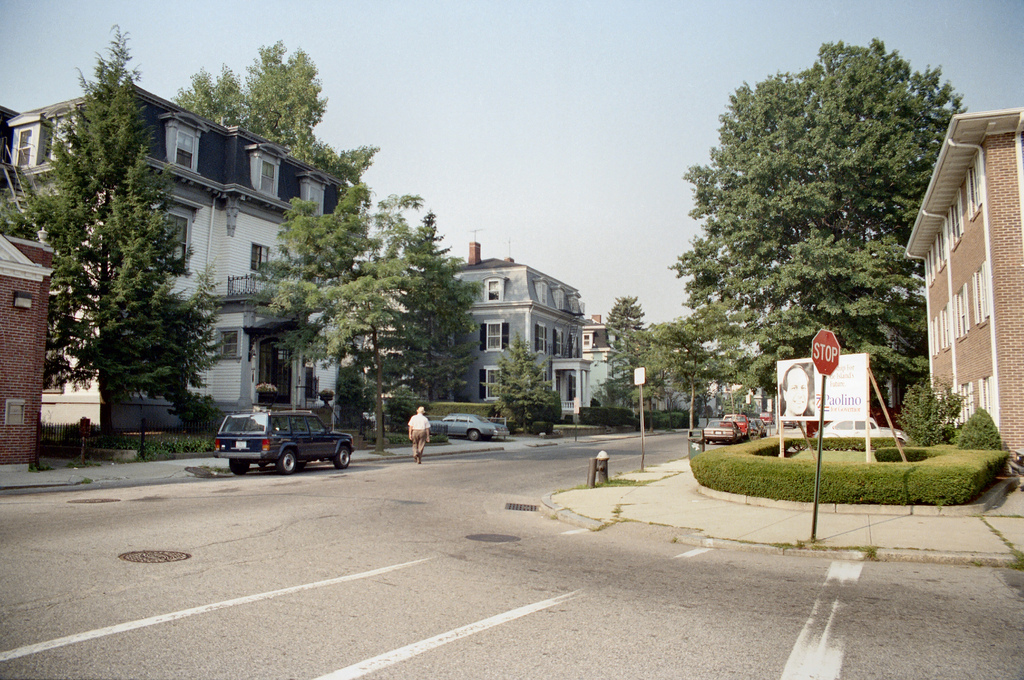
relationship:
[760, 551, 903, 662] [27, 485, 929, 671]
lines on street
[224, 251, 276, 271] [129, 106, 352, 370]
window on a house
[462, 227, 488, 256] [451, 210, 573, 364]
chimney on a house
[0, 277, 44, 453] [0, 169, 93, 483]
wall on side of a building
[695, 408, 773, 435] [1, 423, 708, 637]
cars parked on side of street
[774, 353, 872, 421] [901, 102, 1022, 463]
billboard beside building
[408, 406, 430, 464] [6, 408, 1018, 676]
man walking on street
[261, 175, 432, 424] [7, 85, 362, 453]
tree in front of house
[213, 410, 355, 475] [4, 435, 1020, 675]
jeep parked on side of street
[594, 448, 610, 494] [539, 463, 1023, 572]
fire hydrant near street curb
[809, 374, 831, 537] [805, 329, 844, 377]
pole holding up stop sign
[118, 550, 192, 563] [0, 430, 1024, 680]
cover on road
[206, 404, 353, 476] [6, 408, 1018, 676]
jeep parked on street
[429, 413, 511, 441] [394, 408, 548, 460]
car parked in driveway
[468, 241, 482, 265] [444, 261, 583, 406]
chimney on house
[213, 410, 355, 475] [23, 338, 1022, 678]
jeep on street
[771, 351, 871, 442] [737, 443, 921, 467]
billboard on lawn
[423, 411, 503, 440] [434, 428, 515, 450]
car on driveway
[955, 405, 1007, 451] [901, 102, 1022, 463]
bush along building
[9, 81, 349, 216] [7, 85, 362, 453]
upper level of house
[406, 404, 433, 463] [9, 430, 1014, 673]
man on road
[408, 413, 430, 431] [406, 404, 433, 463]
shirt on man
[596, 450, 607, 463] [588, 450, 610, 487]
top on fire hydrant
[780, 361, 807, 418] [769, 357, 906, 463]
man on sign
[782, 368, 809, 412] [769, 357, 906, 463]
face on sign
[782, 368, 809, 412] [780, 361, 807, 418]
face of man